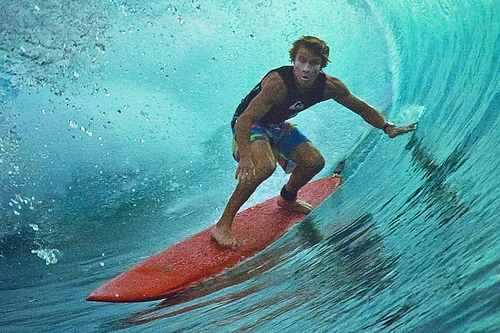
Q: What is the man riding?
A: A wave.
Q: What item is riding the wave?
A: A surfboard.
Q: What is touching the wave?
A: A hand.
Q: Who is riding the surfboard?
A: A man.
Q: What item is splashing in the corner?
A: Water.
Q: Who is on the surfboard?
A: The man.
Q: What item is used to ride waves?
A: A surfboard.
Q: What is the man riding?
A: A wave.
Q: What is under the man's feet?
A: Red surfboard.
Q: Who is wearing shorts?
A: Surfer.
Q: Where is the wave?
A: In the ocean.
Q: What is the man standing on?
A: A surfboard.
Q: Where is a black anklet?
A: On man's left ankle.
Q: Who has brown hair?
A: The surfer.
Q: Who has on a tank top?
A: Man surfing.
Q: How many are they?
A: 1.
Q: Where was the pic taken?
A: In the ocean.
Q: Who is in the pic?
A: A man.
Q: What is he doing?
A: Surfing.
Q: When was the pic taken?
A: During the day.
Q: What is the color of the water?
A: Blue.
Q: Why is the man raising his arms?
A: For balance.